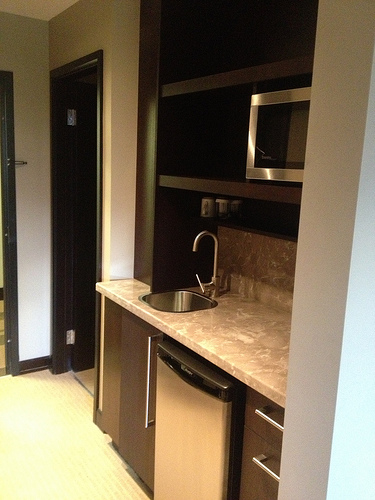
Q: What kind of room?
A: A kitchen.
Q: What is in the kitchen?
A: A sink.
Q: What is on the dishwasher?
A: A panel.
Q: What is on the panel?
A: Buttons.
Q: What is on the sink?
A: The faucet.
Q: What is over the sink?
A: A microwave.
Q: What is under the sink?
A: A cabinet.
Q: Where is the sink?
A: On the counter.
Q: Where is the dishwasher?
A: Below the sink.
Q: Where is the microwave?
A: Above the sink.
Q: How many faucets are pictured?
A: One.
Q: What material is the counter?
A: Granite.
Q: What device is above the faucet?
A: Microwave.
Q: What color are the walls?
A: White.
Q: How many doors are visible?
A: One.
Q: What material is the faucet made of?
A: Metal.